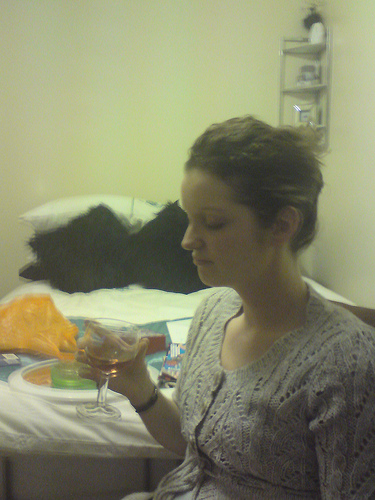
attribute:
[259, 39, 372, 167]
shelf — metal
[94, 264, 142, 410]
glass — clear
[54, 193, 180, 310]
pillows — piled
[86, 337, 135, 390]
glass — clear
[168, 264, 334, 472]
sweater — grey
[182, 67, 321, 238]
hair — brown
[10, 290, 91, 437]
bag — yellow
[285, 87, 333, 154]
frame — yellow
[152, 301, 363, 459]
shirt — grey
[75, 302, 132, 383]
glass — clear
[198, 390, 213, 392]
button — plastic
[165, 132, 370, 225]
hair — brown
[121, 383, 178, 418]
watch — black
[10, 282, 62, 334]
bag — orange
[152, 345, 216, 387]
book — closed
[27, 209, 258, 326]
pillows — black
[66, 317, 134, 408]
glass — clear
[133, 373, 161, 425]
bracelet — black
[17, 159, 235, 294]
pillows — black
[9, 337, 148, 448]
tray — white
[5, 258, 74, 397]
bag — yellow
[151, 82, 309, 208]
hair — brown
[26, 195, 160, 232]
pillow — white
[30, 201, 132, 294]
pillow — black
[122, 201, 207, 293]
pillow — black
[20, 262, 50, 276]
pillow — black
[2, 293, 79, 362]
bag — yellow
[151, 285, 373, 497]
sweater — grey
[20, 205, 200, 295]
pillows — black, fury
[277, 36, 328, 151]
shelf — rack, iron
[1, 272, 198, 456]
sheets — white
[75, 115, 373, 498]
woman — alone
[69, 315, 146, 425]
glass — large